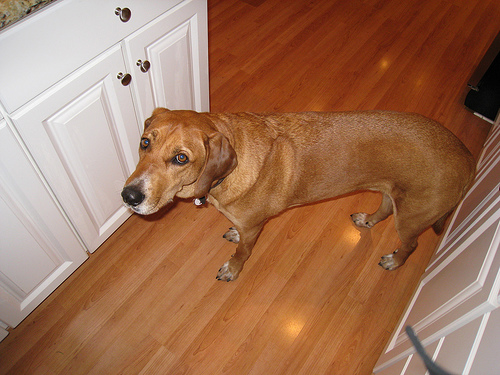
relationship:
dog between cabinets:
[121, 105, 477, 284] [4, 6, 498, 371]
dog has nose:
[121, 105, 477, 284] [119, 183, 149, 209]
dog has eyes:
[121, 105, 477, 284] [135, 133, 197, 166]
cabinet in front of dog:
[0, 3, 209, 348] [121, 105, 477, 284]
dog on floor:
[121, 105, 477, 284] [2, 5, 499, 365]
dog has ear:
[107, 90, 476, 264] [183, 122, 241, 199]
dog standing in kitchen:
[121, 105, 477, 284] [0, 5, 497, 373]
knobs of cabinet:
[108, 5, 159, 90] [0, 3, 209, 348]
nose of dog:
[119, 181, 144, 205] [121, 105, 477, 284]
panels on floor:
[18, 202, 221, 368] [2, 5, 499, 365]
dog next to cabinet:
[121, 105, 477, 284] [0, 3, 209, 348]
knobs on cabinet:
[111, 7, 151, 88] [0, 3, 209, 348]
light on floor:
[336, 229, 356, 246] [201, 283, 263, 334]